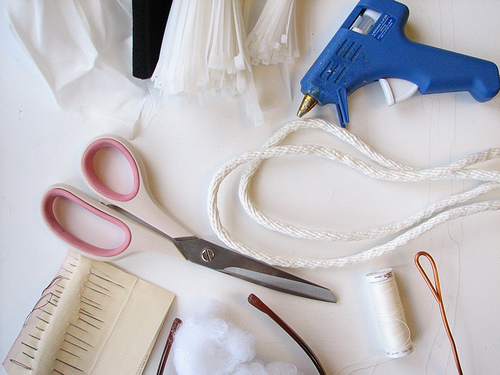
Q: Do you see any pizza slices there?
A: No, there are no pizza slices.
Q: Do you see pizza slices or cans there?
A: No, there are no pizza slices or cans.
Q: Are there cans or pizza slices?
A: No, there are no pizza slices or cans.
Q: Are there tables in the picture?
A: Yes, there is a table.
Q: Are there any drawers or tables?
A: Yes, there is a table.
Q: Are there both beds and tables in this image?
A: No, there is a table but no beds.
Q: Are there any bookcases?
A: No, there are no bookcases.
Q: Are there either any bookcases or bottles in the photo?
A: No, there are no bookcases or bottles.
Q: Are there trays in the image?
A: No, there are no trays.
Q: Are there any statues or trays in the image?
A: No, there are no trays or statues.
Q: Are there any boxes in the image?
A: No, there are no boxes.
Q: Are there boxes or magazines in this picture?
A: No, there are no boxes or magazines.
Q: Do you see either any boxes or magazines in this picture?
A: No, there are no boxes or magazines.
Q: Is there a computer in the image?
A: No, there are no computers.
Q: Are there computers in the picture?
A: No, there are no computers.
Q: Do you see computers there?
A: No, there are no computers.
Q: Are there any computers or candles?
A: No, there are no computers or candles.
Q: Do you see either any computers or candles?
A: No, there are no computers or candles.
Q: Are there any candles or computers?
A: No, there are no computers or candles.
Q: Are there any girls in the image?
A: No, there are no girls.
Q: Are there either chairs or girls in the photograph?
A: No, there are no girls or chairs.